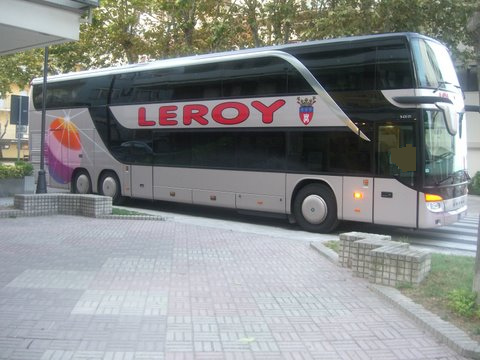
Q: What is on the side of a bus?
A: Sign.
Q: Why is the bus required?
A: Travel.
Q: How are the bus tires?
A: Large.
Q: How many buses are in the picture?
A: One.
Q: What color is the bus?
A: White.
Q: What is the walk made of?
A: Bricks.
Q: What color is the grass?
A: Green.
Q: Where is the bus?
A: On the road.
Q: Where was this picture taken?
A: Outside a building.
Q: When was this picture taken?
A: During the day.